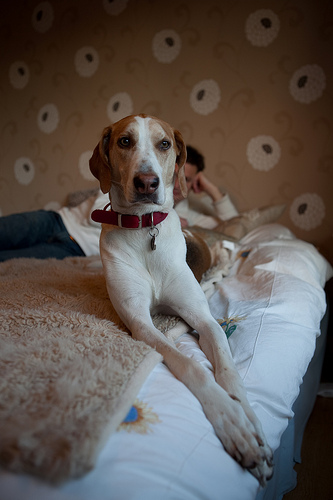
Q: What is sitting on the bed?
A: A dog.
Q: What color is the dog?
A: White and brown.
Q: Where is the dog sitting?
A: On a bed.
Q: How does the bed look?
A: Made and neat.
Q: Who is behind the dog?
A: A man.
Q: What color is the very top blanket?
A: Brown.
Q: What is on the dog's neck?
A: A collar.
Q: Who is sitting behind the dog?
A: A man.